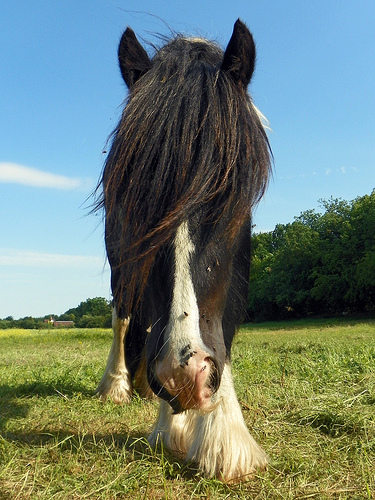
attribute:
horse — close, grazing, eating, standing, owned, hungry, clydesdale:
[97, 18, 273, 482]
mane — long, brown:
[85, 40, 274, 315]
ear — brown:
[118, 29, 153, 92]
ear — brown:
[221, 18, 256, 90]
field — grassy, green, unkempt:
[1, 319, 375, 499]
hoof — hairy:
[190, 425, 269, 477]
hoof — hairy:
[146, 411, 195, 452]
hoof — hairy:
[92, 371, 129, 406]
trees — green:
[250, 190, 373, 319]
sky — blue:
[1, 4, 374, 316]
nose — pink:
[161, 370, 211, 409]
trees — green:
[79, 312, 121, 327]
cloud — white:
[2, 161, 74, 193]